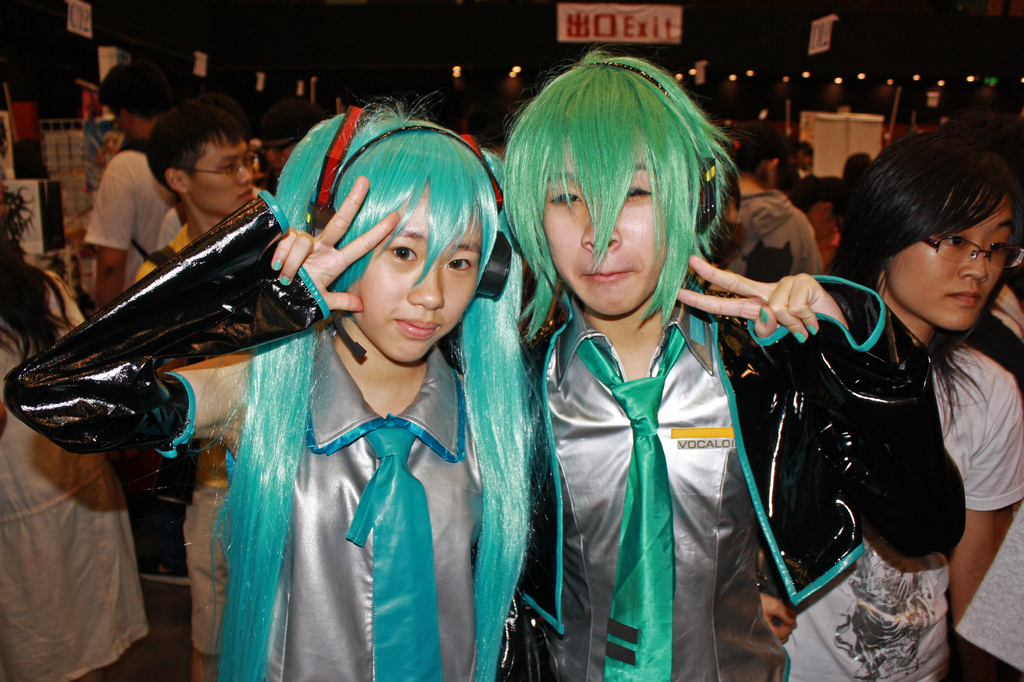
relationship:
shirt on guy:
[521, 314, 779, 667] [478, 37, 863, 668]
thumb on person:
[299, 286, 380, 321] [37, 96, 537, 645]